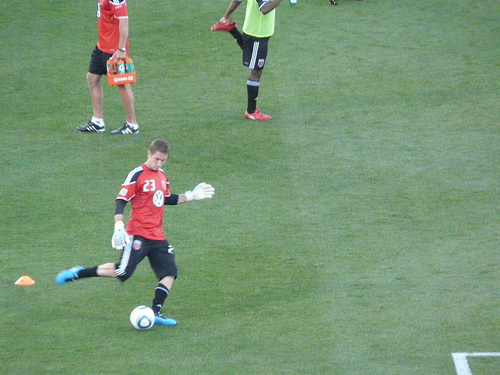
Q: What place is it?
A: It is a field.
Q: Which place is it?
A: It is a field.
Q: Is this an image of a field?
A: Yes, it is showing a field.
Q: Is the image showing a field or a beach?
A: It is showing a field.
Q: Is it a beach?
A: No, it is a field.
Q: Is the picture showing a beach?
A: No, the picture is showing a field.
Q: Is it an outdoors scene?
A: Yes, it is outdoors.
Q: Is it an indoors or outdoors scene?
A: It is outdoors.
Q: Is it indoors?
A: No, it is outdoors.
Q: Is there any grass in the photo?
A: Yes, there is grass.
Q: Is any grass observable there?
A: Yes, there is grass.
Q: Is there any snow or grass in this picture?
A: Yes, there is grass.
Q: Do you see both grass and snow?
A: No, there is grass but no snow.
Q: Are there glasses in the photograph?
A: No, there are no glasses.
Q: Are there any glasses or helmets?
A: No, there are no glasses or helmets.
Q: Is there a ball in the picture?
A: Yes, there is a ball.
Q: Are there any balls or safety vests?
A: Yes, there is a ball.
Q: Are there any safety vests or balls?
A: Yes, there is a ball.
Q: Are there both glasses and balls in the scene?
A: No, there is a ball but no glasses.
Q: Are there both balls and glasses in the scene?
A: No, there is a ball but no glasses.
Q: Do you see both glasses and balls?
A: No, there is a ball but no glasses.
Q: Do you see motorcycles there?
A: No, there are no motorcycles.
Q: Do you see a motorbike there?
A: No, there are no motorcycles.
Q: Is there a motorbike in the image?
A: No, there are no motorcycles.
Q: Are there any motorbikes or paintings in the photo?
A: No, there are no motorbikes or paintings.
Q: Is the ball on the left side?
A: Yes, the ball is on the left of the image.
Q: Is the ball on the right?
A: No, the ball is on the left of the image.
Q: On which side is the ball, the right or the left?
A: The ball is on the left of the image.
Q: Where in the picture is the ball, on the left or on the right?
A: The ball is on the left of the image.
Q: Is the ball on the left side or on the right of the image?
A: The ball is on the left of the image.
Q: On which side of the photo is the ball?
A: The ball is on the left of the image.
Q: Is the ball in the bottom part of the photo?
A: Yes, the ball is in the bottom of the image.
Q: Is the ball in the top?
A: No, the ball is in the bottom of the image.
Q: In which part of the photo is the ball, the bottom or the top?
A: The ball is in the bottom of the image.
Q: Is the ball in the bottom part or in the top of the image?
A: The ball is in the bottom of the image.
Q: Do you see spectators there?
A: No, there are no spectators.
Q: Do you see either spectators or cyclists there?
A: No, there are no spectators or cyclists.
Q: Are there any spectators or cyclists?
A: No, there are no spectators or cyclists.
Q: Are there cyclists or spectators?
A: No, there are no spectators or cyclists.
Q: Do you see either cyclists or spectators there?
A: No, there are no spectators or cyclists.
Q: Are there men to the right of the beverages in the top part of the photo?
A: Yes, there is a man to the right of the beverages.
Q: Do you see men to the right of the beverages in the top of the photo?
A: Yes, there is a man to the right of the beverages.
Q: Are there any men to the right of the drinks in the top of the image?
A: Yes, there is a man to the right of the beverages.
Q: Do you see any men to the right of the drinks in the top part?
A: Yes, there is a man to the right of the beverages.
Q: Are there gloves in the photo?
A: Yes, there are gloves.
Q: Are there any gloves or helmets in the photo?
A: Yes, there are gloves.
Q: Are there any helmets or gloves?
A: Yes, there are gloves.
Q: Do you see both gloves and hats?
A: No, there are gloves but no hats.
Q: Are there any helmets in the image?
A: No, there are no helmets.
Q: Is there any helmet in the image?
A: No, there are no helmets.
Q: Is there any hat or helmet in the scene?
A: No, there are no helmets or hats.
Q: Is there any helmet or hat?
A: No, there are no helmets or hats.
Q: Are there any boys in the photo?
A: No, there are no boys.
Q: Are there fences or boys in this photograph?
A: No, there are no boys or fences.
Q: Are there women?
A: No, there are no women.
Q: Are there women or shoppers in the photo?
A: No, there are no women or shoppers.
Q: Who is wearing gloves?
A: The man is wearing gloves.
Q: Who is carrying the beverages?
A: The man is carrying the beverages.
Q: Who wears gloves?
A: The man wears gloves.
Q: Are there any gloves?
A: Yes, there are gloves.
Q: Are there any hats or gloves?
A: Yes, there are gloves.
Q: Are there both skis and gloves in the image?
A: No, there are gloves but no skis.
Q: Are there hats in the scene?
A: No, there are no hats.